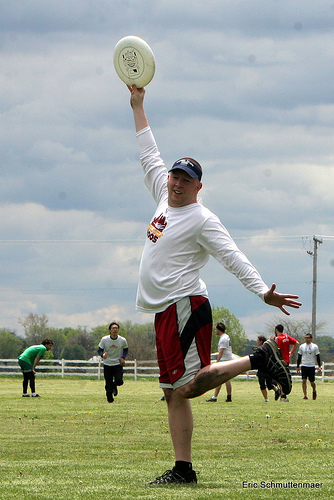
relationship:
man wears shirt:
[17, 338, 53, 400] [18, 344, 48, 367]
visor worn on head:
[168, 158, 202, 182] [166, 157, 203, 206]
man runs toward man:
[97, 322, 131, 404] [124, 83, 302, 485]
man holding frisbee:
[124, 83, 302, 485] [113, 36, 156, 89]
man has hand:
[124, 83, 302, 485] [263, 283, 303, 317]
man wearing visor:
[124, 83, 302, 485] [168, 158, 202, 182]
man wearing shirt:
[17, 338, 53, 400] [18, 344, 48, 367]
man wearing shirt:
[97, 322, 131, 404] [98, 336, 130, 369]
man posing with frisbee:
[124, 83, 302, 485] [113, 36, 156, 89]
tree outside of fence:
[0, 327, 27, 359] [2, 359, 334, 384]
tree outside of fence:
[17, 312, 50, 348] [2, 359, 334, 384]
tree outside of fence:
[59, 342, 87, 371] [2, 359, 334, 384]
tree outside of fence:
[211, 305, 248, 358] [2, 359, 334, 384]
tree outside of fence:
[262, 314, 324, 365] [2, 359, 334, 384]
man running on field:
[97, 322, 131, 404] [0, 380, 332, 499]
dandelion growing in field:
[264, 414, 270, 427] [0, 380, 332, 499]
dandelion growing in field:
[303, 423, 311, 430] [0, 380, 332, 499]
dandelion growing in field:
[315, 437, 320, 445] [0, 380, 332, 499]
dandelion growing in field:
[86, 409, 93, 416] [0, 380, 332, 499]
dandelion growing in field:
[292, 445, 298, 450] [0, 380, 332, 499]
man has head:
[124, 83, 302, 485] [166, 157, 203, 206]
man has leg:
[124, 83, 302, 485] [162, 386, 194, 463]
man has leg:
[124, 83, 302, 485] [175, 355, 252, 400]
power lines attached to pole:
[1, 233, 333, 249] [307, 234, 324, 346]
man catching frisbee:
[124, 83, 302, 485] [113, 36, 156, 89]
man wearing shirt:
[97, 322, 131, 404] [95, 348, 127, 359]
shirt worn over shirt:
[98, 336, 130, 369] [95, 348, 127, 359]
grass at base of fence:
[1, 373, 332, 383] [2, 359, 334, 384]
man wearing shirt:
[295, 333, 324, 401] [297, 343, 321, 369]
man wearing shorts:
[295, 333, 324, 401] [301, 366, 317, 382]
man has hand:
[124, 83, 302, 485] [126, 83, 147, 110]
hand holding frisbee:
[126, 83, 147, 110] [113, 36, 156, 89]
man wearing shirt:
[274, 325, 301, 364] [275, 335, 298, 364]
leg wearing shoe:
[175, 355, 252, 400] [252, 337, 294, 397]